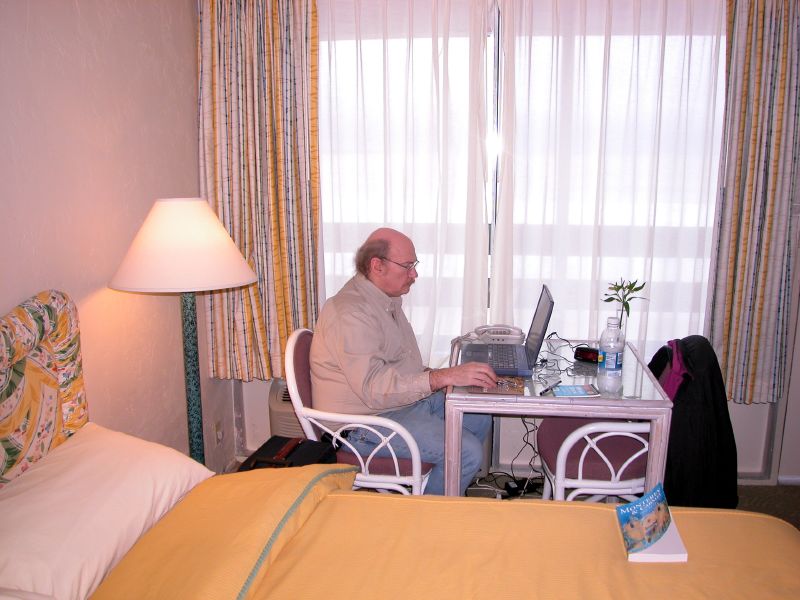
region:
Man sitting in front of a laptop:
[314, 207, 499, 503]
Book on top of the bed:
[608, 470, 688, 580]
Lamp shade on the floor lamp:
[100, 183, 271, 320]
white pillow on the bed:
[12, 403, 212, 581]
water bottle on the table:
[593, 317, 629, 394]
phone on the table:
[456, 315, 524, 339]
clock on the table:
[565, 338, 616, 371]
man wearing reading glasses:
[374, 256, 420, 274]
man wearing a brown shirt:
[297, 273, 439, 407]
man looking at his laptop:
[314, 224, 552, 492]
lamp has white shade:
[114, 192, 263, 464]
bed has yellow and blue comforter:
[2, 287, 798, 592]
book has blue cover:
[614, 487, 691, 573]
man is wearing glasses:
[368, 248, 421, 284]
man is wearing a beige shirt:
[311, 276, 440, 416]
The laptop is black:
[467, 285, 559, 385]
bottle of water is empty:
[596, 315, 629, 398]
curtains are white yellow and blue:
[195, 2, 798, 416]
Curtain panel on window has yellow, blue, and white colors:
[193, 3, 313, 371]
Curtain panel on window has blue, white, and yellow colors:
[705, 0, 798, 405]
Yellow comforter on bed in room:
[103, 461, 797, 599]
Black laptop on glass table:
[456, 285, 556, 381]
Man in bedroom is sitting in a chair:
[284, 231, 480, 496]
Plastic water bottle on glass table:
[593, 321, 628, 394]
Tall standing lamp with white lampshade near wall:
[101, 189, 251, 464]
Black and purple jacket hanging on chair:
[647, 335, 745, 507]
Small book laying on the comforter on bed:
[612, 485, 689, 567]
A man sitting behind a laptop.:
[294, 207, 567, 499]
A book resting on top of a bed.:
[611, 469, 703, 577]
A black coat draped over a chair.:
[565, 338, 757, 525]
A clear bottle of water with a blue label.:
[592, 317, 622, 395]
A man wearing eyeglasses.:
[309, 216, 485, 512]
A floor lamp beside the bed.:
[102, 193, 275, 463]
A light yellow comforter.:
[92, 455, 793, 595]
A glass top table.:
[443, 312, 685, 512]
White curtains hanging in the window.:
[317, 13, 718, 379]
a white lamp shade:
[109, 198, 256, 295]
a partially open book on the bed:
[617, 484, 690, 565]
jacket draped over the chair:
[649, 333, 737, 504]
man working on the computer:
[308, 227, 486, 493]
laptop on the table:
[461, 285, 550, 377]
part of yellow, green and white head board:
[0, 287, 84, 472]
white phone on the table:
[445, 323, 520, 367]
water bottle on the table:
[598, 317, 625, 395]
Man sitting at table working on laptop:
[285, 227, 671, 491]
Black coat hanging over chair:
[650, 333, 739, 510]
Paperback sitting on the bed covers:
[614, 487, 691, 563]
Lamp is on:
[110, 197, 258, 461]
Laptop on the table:
[460, 286, 556, 383]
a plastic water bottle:
[596, 316, 623, 391]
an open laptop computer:
[457, 284, 553, 376]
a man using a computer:
[308, 225, 553, 491]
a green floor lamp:
[105, 193, 259, 465]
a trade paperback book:
[614, 483, 689, 561]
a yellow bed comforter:
[89, 459, 796, 598]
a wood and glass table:
[445, 334, 670, 494]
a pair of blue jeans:
[344, 390, 489, 495]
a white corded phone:
[449, 325, 524, 346]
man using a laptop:
[274, 222, 567, 494]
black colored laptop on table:
[465, 286, 557, 395]